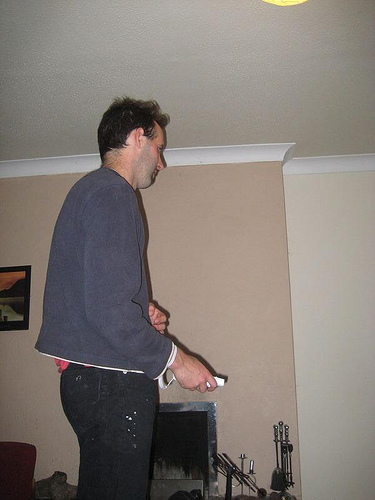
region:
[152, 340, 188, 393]
a white wrist strap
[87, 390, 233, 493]
a small, dirty fireplace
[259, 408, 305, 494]
a few fireplace tools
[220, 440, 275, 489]
a silver candle holder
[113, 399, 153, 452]
some white spots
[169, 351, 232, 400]
a nintendo wii remote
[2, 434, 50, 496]
a dark red chair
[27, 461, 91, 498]
large piece of fire wood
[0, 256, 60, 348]
a black picture frame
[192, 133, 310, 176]
some white crown molding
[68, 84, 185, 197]
A man's head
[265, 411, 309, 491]
Fireplace tools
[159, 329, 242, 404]
A hand holding a Wii remote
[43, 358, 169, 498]
Black pants spattered with paint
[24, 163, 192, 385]
A blue jersey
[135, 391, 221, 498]
A fireplace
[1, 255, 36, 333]
Part of a painting of a lake and mountain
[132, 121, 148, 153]
A man's ear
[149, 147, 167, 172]
A man's nose in profile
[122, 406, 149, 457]
Paint splatters on black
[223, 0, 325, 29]
The ceiling light can be seen.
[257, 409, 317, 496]
Fireplace tools in the background.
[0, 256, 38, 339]
A picture hanging on the wall.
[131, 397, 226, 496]
The fireplace does not appear to be in use.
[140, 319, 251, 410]
Holding a Wii remote.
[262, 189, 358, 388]
The walls are two different colors.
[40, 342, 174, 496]
Man is wearing back jeans.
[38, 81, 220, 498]
Photo taken at a low angle.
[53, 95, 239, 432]
Getting ready to play Wii.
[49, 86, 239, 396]
Man wearing grey shirt.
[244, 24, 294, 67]
part of a ceiling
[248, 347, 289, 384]
part of a wall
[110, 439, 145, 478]
part of a jeans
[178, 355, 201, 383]
part of a hand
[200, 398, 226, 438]
part of a wall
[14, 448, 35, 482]
edge of a chair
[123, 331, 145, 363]
part of a sleeve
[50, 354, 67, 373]
part of a shirt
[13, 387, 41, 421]
part of a wall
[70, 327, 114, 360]
part of a jumper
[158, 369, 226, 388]
white wii remote control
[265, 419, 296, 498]
metal fireplace tools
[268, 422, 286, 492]
metal fireplace brush with bristles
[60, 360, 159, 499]
pair of black jeans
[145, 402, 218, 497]
black metal fireplace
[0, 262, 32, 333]
black framed painting on wall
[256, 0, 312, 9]
yellow ceiling light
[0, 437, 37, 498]
red chair against back wall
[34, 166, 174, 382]
long sleeve grey cotton sweater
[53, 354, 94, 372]
pink shirt underneath grey sweater